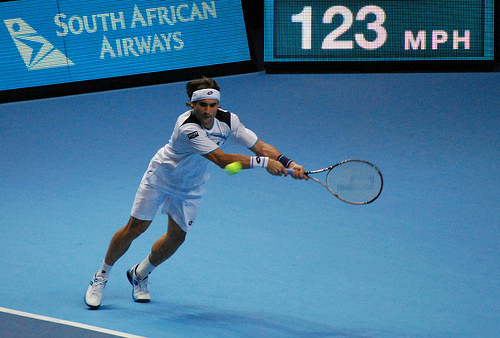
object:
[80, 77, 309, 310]
man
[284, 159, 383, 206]
racket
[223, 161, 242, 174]
tennis ball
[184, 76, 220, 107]
hair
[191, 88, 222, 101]
headband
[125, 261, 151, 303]
tennis shoes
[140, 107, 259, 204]
shirt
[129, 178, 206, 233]
shorts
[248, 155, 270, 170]
wristband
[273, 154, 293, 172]
wristband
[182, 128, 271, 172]
arm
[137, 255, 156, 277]
sock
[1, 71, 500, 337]
floor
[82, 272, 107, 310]
tennis shoe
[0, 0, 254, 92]
advertisement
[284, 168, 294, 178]
handle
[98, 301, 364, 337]
shadow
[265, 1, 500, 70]
speed sign